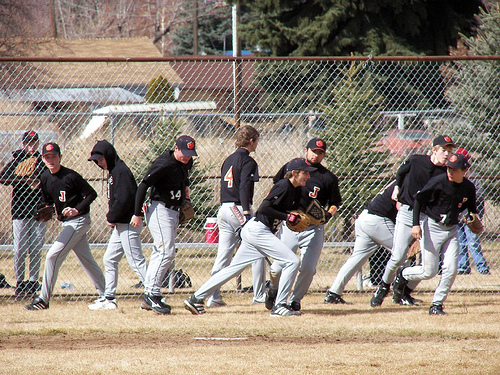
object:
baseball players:
[7, 130, 495, 306]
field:
[205, 344, 302, 363]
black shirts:
[395, 154, 447, 206]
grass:
[21, 354, 80, 375]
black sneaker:
[183, 294, 207, 315]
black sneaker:
[142, 295, 171, 315]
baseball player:
[129, 135, 198, 314]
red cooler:
[203, 217, 219, 243]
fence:
[302, 80, 372, 106]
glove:
[286, 210, 311, 232]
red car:
[360, 129, 437, 156]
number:
[170, 190, 182, 201]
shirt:
[143, 150, 194, 206]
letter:
[59, 191, 66, 202]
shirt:
[40, 165, 98, 222]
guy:
[22, 142, 105, 311]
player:
[184, 158, 328, 318]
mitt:
[305, 199, 326, 225]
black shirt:
[220, 148, 259, 211]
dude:
[87, 139, 148, 311]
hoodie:
[87, 139, 137, 223]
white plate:
[192, 337, 249, 341]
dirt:
[90, 332, 147, 352]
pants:
[144, 199, 180, 296]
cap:
[442, 154, 467, 171]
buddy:
[0, 130, 47, 297]